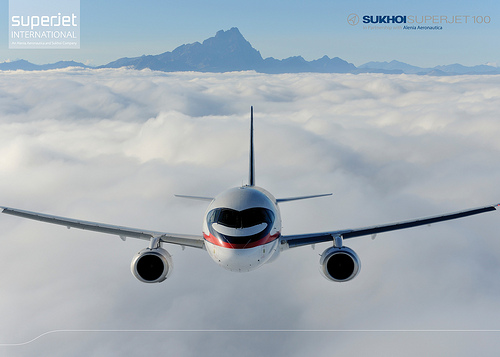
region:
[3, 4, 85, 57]
The lettering is white.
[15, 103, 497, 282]
The plane is white.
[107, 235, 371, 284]
The plane has two jets.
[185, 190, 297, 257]
The front is black and red.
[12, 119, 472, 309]
The plane is large.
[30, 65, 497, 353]
The clouds are white.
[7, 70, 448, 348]
The clouds are fluffy.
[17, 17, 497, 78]
The mountains are far away.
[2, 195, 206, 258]
The wing is long.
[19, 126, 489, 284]
The plane is in the air.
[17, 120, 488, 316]
The plane is flying.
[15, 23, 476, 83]
The mountain is far away.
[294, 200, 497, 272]
The wing has a shadow.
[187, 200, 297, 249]
The front of the plane is black and red.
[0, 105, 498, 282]
airplane is flying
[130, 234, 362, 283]
engines on airplane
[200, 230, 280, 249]
red line on airplane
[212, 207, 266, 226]
windshield on airplane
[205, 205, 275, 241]
black line around winshield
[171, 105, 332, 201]
tail wings at back of airplane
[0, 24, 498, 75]
tall mountains behind airplane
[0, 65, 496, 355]
several clouds under airplane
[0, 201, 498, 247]
long wings on airplane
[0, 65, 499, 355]
clouds are white and fluffy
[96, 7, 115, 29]
this is the sky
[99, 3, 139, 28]
the sky is blue in color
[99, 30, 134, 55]
the sky has clouds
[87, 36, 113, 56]
the clouds are white in color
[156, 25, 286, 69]
this is a mountain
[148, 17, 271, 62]
the mountain is high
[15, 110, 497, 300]
this is an airplane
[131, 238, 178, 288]
this is a propeller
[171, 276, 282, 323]
these are some clouds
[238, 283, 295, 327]
the clouds are white in color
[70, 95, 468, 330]
plane in the air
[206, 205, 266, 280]
nose of the plane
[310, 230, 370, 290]
engine of the plane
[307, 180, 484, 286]
wing of the plane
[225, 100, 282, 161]
tail of the plane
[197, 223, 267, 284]
stripes on the plane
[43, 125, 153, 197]
clouds under the plane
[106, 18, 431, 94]
mountain range in the background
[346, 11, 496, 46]
name in top right corner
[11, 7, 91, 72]
name in top left corner of photo